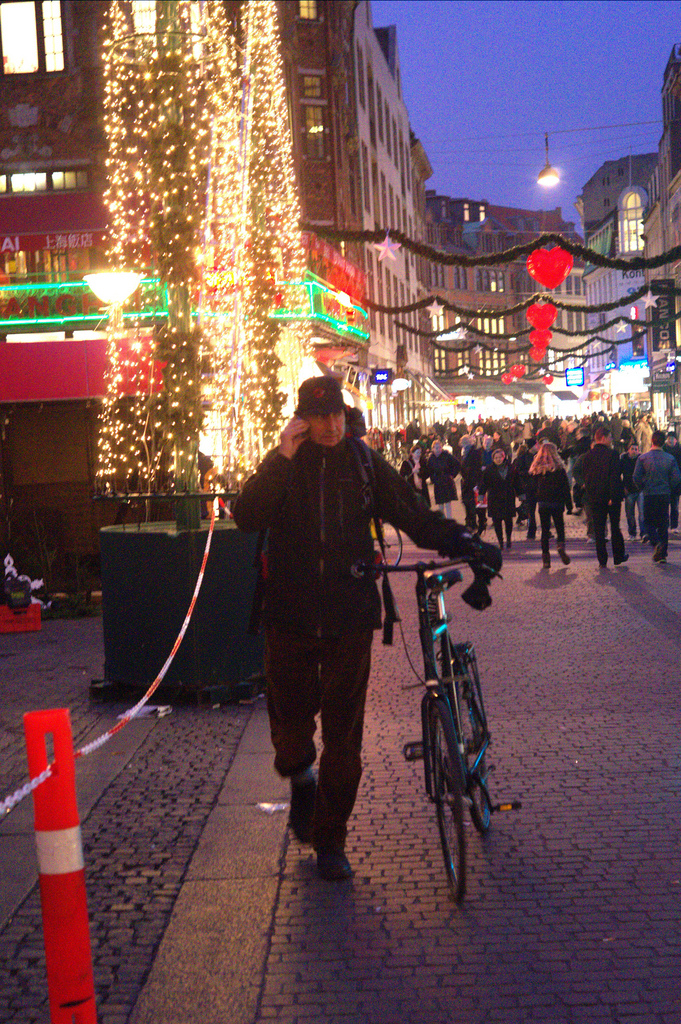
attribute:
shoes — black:
[305, 817, 354, 889]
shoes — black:
[282, 765, 359, 881]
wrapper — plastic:
[254, 794, 283, 827]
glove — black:
[458, 535, 517, 589]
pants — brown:
[260, 605, 371, 861]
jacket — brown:
[233, 407, 465, 631]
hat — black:
[291, 376, 346, 415]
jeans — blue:
[532, 495, 571, 570]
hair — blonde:
[527, 438, 561, 477]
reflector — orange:
[488, 797, 532, 830]